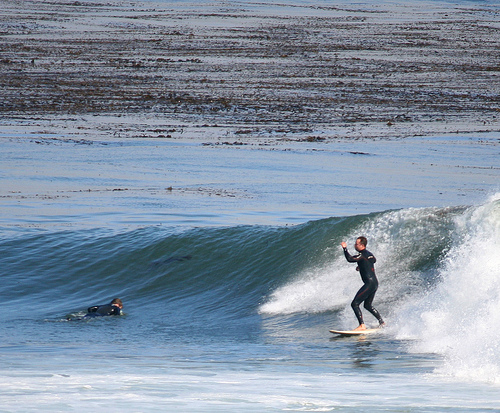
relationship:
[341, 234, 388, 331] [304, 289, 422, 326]
man on board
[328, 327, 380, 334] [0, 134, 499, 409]
board in water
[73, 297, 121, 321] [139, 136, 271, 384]
dog in water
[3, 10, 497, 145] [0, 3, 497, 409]
seaweed floating in water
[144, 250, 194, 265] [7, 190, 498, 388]
seaweed in wave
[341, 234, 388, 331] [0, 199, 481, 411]
man in water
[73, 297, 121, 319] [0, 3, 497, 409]
dog in water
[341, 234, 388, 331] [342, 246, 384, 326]
man in suit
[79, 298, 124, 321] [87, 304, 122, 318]
man in wetsuit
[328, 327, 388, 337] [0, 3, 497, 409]
surfboard in water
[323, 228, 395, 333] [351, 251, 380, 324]
man in a wetsuit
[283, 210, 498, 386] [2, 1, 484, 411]
spray in ocean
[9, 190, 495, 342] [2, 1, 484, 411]
wave in ocean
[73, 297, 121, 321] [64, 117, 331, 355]
dog in water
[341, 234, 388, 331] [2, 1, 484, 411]
man in ocean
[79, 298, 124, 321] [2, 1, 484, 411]
man in ocean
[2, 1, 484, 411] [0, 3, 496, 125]
ocean filled with seaweed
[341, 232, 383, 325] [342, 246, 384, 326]
man wearing suit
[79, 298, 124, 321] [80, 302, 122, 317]
man wearing wetsuit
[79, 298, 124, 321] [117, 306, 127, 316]
man laying down on surfboard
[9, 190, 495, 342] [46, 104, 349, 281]
wave in ocean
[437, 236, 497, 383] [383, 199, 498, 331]
foam crashed by wave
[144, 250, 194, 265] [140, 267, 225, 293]
seaweed floating in water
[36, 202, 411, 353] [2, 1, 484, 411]
two people surfing in ocean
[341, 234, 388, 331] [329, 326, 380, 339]
man standing on surfboard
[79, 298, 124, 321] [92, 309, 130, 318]
man laying down on surfboard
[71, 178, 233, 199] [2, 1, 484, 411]
weed on ocean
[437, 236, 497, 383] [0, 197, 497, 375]
foam of wave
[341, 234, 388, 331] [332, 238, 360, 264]
man has arms